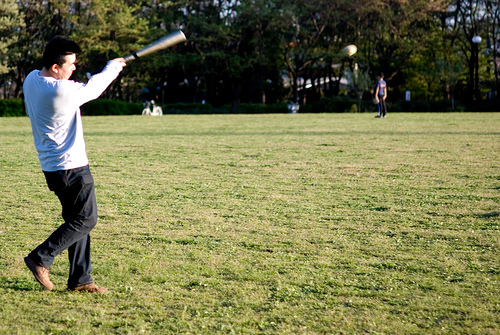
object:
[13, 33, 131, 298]
person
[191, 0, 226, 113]
tree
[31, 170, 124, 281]
pants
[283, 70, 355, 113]
white house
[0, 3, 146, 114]
tree line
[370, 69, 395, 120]
person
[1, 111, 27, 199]
green grass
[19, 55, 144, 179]
shirt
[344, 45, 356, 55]
ball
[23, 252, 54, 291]
shoe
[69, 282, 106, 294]
shoe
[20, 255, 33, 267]
heel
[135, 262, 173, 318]
grass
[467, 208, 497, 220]
shadow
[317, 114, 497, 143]
ground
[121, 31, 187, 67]
baseball bat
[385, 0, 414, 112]
tree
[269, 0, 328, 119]
tree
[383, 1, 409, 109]
tree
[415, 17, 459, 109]
distance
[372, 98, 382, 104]
glove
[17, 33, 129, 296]
man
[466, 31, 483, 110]
lamp pole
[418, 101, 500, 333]
field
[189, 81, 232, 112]
bushes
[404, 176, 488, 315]
grass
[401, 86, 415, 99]
sign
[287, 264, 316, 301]
grass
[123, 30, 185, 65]
silver bat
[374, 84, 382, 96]
arms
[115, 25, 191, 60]
bat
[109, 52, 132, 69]
hand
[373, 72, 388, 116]
pitcher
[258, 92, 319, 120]
line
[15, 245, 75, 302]
shoe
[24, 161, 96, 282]
pants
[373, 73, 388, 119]
man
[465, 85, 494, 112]
bushes